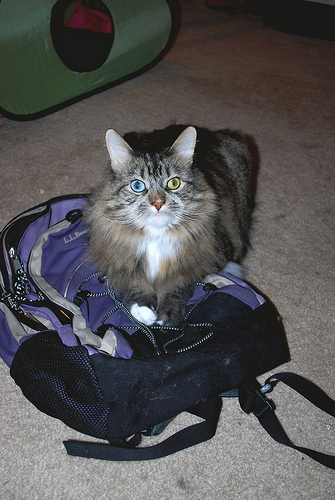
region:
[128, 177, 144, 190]
The cats blue eye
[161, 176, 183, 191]
The cats brown ere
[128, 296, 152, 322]
The cats white paw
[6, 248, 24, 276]
The zipper on the backpack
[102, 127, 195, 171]
The cats ears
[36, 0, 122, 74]
Opening to the tent in the background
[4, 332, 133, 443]
The mesh pocket on the back pack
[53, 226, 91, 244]
L.L Bean written on backpack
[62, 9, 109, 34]
Red item in background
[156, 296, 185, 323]
Cats gray paw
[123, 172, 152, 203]
cat has one eye that is blue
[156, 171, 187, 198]
cat has a yellow eye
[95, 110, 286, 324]
cat is lying on a backpack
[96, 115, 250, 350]
cat is brown, black and white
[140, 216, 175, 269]
cat's chest is white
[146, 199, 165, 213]
cat's nose is pink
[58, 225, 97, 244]
L.L. Bean is written on the backpack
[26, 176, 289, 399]
backpack is blue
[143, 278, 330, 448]
backpack is lying on the carpet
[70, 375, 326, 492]
straps on the backpack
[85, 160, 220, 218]
a cat with a blue and yellow eye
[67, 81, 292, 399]
a cat sitting on a bag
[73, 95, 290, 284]
a grey and white cat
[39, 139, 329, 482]
a purple and black bookbag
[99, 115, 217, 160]
a cats two ears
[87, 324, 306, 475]
straps on a bookbag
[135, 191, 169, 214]
a cats pink nose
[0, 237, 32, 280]
a zipper on a bookbag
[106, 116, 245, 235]
the head of a cat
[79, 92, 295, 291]
a very furry cat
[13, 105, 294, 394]
a cat lying on a backpack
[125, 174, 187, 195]
the eyes of a cat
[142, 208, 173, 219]
the mouth of a cat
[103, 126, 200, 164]
the ears of a cat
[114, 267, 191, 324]
the front legs of a cat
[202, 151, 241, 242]
the fur of a cat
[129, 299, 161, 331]
the paw of a cat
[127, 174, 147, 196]
the eye of a cat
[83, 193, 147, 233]
the whiskers of a cat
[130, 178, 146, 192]
blue eye of a cat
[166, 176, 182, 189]
yellow eye of a cat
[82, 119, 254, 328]
A furry cat with mismatched eyes.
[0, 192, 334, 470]
A black and purple backpack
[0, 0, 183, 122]
A green cat house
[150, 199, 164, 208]
nose of a cat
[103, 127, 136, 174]
long ear of cat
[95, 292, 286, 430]
Fur on top of bag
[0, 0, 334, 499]
grey colored carpet on floor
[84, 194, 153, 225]
long whiskers on cat